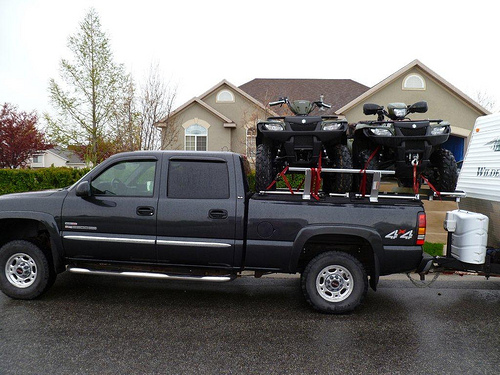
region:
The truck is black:
[0, 145, 433, 313]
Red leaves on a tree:
[0, 100, 57, 165]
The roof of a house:
[235, 75, 370, 117]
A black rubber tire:
[297, 247, 368, 312]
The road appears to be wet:
[0, 285, 496, 370]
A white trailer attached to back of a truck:
[405, 110, 496, 282]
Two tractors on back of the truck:
[1, 87, 451, 309]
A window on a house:
[180, 110, 211, 147]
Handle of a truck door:
[130, 201, 155, 218]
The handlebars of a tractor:
[262, 90, 333, 112]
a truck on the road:
[72, 95, 454, 368]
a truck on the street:
[86, 106, 487, 355]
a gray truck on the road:
[85, 48, 428, 368]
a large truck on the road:
[110, 129, 371, 364]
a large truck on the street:
[57, 102, 406, 349]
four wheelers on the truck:
[153, 55, 496, 307]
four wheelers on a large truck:
[219, 101, 493, 248]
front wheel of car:
[0, 237, 55, 307]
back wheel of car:
[295, 240, 371, 317]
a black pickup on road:
[5, 140, 435, 320]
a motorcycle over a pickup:
[236, 80, 351, 205]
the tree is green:
[33, 3, 148, 199]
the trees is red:
[0, 99, 52, 181]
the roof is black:
[235, 69, 372, 118]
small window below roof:
[336, 58, 490, 118]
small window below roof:
[191, 75, 255, 107]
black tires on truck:
[305, 270, 422, 307]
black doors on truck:
[74, 140, 222, 277]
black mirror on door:
[72, 167, 117, 201]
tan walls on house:
[186, 71, 468, 148]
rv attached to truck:
[450, 121, 498, 313]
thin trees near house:
[61, 26, 175, 166]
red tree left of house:
[1, 103, 65, 163]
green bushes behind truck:
[8, 170, 78, 192]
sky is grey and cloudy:
[161, 6, 282, 68]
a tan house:
[168, 78, 496, 168]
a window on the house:
[190, 123, 205, 147]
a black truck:
[6, 143, 475, 295]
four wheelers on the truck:
[251, 96, 448, 193]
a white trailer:
[447, 108, 490, 270]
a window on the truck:
[167, 162, 222, 197]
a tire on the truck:
[313, 246, 352, 313]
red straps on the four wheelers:
[353, 139, 383, 199]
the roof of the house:
[244, 75, 365, 112]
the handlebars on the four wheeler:
[266, 91, 331, 116]